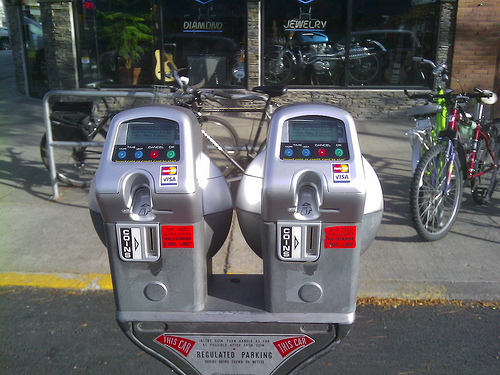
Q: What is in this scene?
A: Twin coin parking meters.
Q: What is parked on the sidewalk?
A: A silver bicycle.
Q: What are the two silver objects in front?
A: Parking meters.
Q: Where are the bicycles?
A: On the sidewalk.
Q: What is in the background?
A: Storefront windows.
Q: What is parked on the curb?
A: Bicycles.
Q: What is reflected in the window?
A: A bike.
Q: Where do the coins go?
A: In the slots in the meters.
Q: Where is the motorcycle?
A: Parked in the store window.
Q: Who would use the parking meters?
A: People who park outside.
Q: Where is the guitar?
A: Behind the meters in a store window.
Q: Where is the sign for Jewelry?
A: In the store window.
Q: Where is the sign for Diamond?
A: Hanging in the store window.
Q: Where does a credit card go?
A: In the slot in the meter.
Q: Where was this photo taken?
A: Near a city street.